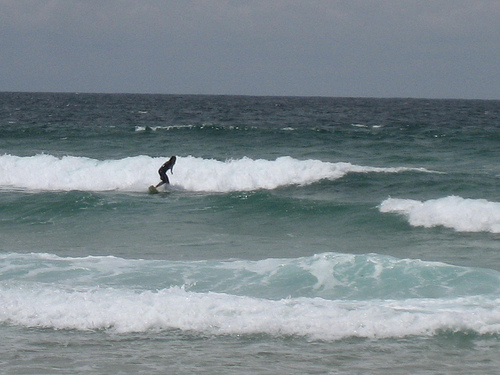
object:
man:
[149, 156, 178, 194]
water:
[267, 109, 384, 232]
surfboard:
[149, 185, 156, 196]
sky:
[229, 4, 329, 75]